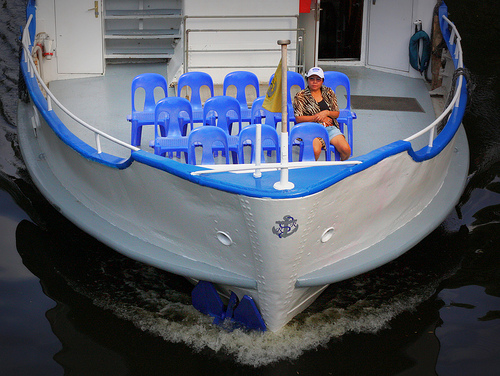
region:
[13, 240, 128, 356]
The water is the color brown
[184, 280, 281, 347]
The propeller on the boat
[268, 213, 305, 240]
The logo on the boat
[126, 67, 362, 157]
The chairs on the boat are blue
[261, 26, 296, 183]
The flag on the boat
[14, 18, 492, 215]
The rim of the boat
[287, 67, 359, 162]
A woman sitting on the chair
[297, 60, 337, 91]
The woman has on a hat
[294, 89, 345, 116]
The woman has on a Hawaiian shirt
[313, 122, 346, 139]
The woman is wearing blue jeans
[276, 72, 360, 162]
Man seating in a a chair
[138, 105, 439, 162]
row of chairs on a boat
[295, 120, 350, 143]
man wearing blue jean shorts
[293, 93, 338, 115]
person wearing a brown shirt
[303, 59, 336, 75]
person wearing a white hat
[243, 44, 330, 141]
Flag on a boat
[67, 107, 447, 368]
Boat in the water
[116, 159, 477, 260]
Blue and white boat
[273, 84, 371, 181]
person on a boat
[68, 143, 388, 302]
boat on the river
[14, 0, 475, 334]
a white and blue boat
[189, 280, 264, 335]
a blue anchor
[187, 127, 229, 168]
a plastic blue chair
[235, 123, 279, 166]
a plastic blue chair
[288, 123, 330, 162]
a plastic blue chair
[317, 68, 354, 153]
a plastic blue chair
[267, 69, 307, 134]
a plastic blue chair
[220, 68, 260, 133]
a plastic blue chair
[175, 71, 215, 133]
a plastic blue chair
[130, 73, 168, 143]
a plastic blue chair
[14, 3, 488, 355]
a white boat in the water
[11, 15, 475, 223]
border of ship is blue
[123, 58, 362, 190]
blue chairs in front of ship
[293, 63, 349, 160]
woman sit on a blue chair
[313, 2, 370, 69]
the door of a boat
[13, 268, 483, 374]
reflection of boat on water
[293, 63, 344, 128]
woman wears white cap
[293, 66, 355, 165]
woman wears blue shorts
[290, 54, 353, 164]
woman has sunglasses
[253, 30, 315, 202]
a flag on top of boat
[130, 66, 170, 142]
Small blue seat on a boat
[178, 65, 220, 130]
Small blue seat on a boat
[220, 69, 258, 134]
Small blue seat on a boat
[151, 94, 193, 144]
Small blue seat on a boat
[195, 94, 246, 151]
Small blue seat on a boat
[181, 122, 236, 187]
Small blue seat on a boat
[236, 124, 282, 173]
Small blue seat on a boat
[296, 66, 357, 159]
PErson sitting on blue seat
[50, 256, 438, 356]
Small wave in the water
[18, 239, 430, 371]
Ripples in the water